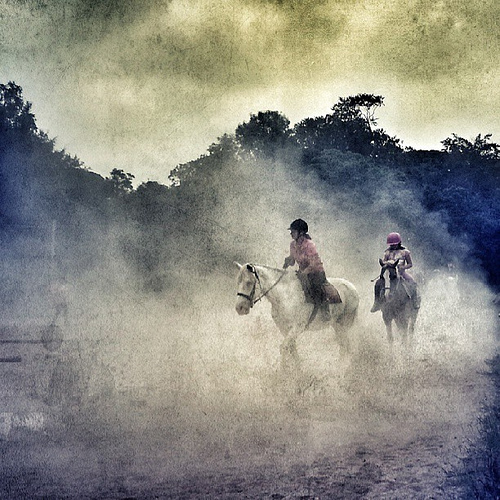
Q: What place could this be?
A: It is a forest.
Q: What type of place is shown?
A: It is a forest.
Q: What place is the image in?
A: It is at the forest.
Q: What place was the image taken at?
A: It was taken at the forest.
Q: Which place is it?
A: It is a forest.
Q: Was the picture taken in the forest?
A: Yes, it was taken in the forest.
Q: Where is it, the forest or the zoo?
A: It is the forest.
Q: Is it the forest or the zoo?
A: It is the forest.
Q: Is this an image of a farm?
A: No, the picture is showing a forest.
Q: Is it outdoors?
A: Yes, it is outdoors.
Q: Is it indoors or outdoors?
A: It is outdoors.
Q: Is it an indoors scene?
A: No, it is outdoors.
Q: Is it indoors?
A: No, it is outdoors.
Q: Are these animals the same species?
A: Yes, all the animals are horses.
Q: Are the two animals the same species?
A: Yes, all the animals are horses.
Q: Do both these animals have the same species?
A: Yes, all the animals are horses.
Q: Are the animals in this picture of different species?
A: No, all the animals are horses.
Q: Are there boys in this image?
A: No, there are no boys.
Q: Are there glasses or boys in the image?
A: No, there are no boys or glasses.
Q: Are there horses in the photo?
A: Yes, there is a horse.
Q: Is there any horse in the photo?
A: Yes, there is a horse.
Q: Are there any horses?
A: Yes, there is a horse.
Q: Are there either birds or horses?
A: Yes, there is a horse.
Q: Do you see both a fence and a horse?
A: No, there is a horse but no fences.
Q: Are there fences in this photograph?
A: No, there are no fences.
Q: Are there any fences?
A: No, there are no fences.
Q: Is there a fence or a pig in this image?
A: No, there are no fences or pigs.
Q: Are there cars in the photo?
A: No, there are no cars.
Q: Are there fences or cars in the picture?
A: No, there are no cars or fences.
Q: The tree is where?
A: The tree is in the forest.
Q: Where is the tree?
A: The tree is in the forest.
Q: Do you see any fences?
A: No, there are no fences.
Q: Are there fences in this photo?
A: No, there are no fences.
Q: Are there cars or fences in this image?
A: No, there are no fences or cars.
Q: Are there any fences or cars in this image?
A: No, there are no fences or cars.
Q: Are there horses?
A: Yes, there is a horse.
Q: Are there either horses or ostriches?
A: Yes, there is a horse.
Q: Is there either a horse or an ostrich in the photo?
A: Yes, there is a horse.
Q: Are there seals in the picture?
A: No, there are no seals.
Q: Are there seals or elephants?
A: No, there are no seals or elephants.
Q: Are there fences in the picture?
A: No, there are no fences.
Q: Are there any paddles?
A: No, there are no paddles.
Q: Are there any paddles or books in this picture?
A: No, there are no paddles or books.